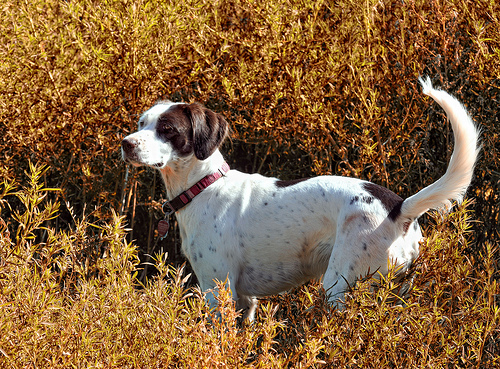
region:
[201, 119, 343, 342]
A dog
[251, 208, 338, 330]
A dog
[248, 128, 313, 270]
A dog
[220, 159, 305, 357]
A dog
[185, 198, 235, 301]
A dog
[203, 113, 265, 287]
A dog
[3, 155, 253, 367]
tall green and brown grass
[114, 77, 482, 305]
white dog with black spots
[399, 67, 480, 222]
dog's curved white tail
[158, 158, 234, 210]
dog's red collar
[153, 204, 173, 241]
dog's red ID tags on a collar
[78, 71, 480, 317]
dog in a field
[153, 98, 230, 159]
large black spot on dog's head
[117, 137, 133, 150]
dog's wet black nose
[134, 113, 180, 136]
dog has eyes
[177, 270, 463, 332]
dog's legs partially hidden in tall grass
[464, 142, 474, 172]
tail of a dog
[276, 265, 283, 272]
body of a dog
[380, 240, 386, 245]
back of a dog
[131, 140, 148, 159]
face of a dog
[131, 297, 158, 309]
leaves of a tree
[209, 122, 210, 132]
ear of a dog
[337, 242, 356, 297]
leg of a dog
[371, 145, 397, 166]
leaves of a tree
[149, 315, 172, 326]
part of a plantation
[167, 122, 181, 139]
eye of a dog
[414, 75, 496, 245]
The dog's tail is visible.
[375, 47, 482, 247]
The dog's tail is visible.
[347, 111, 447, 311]
The dog's tail is visible.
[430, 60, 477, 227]
The dog's tail is visible.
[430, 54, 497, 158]
The dog's tail is visible.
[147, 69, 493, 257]
the dog has tail